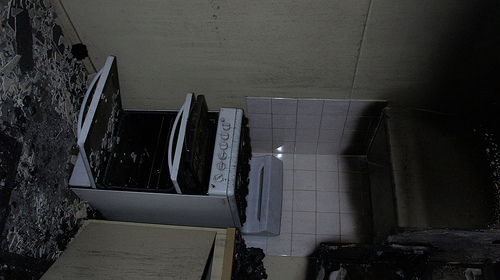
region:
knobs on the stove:
[213, 114, 232, 189]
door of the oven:
[252, 153, 284, 238]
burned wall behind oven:
[12, 38, 72, 130]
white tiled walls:
[280, 101, 340, 143]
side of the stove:
[107, 193, 190, 218]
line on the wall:
[335, 16, 378, 69]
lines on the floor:
[299, 161, 330, 216]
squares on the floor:
[291, 166, 319, 216]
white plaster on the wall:
[32, 65, 64, 99]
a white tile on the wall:
[245, 93, 272, 116]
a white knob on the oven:
[220, 118, 232, 133]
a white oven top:
[241, 148, 289, 240]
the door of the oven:
[66, 48, 134, 188]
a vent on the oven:
[258, 160, 268, 225]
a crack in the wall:
[344, 0, 377, 101]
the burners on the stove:
[228, 106, 255, 226]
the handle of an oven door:
[160, 100, 190, 175]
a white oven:
[58, 31, 296, 246]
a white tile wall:
[238, 85, 395, 263]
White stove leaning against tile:
[55, 54, 282, 237]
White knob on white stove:
[220, 119, 231, 132]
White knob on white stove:
[220, 129, 231, 141]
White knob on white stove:
[218, 138, 230, 150]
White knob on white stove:
[217, 148, 227, 162]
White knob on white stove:
[214, 157, 226, 172]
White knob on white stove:
[212, 170, 225, 183]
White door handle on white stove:
[166, 98, 183, 170]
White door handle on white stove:
[72, 60, 106, 137]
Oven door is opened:
[70, 47, 157, 189]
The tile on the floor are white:
[290, 159, 356, 229]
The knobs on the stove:
[213, 110, 233, 195]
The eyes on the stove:
[233, 108, 258, 230]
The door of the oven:
[73, 52, 130, 192]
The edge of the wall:
[374, 104, 407, 231]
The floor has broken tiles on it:
[4, 21, 71, 237]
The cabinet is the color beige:
[73, 212, 244, 277]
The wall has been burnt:
[303, 218, 493, 278]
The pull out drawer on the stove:
[164, 88, 213, 199]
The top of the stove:
[251, 144, 289, 241]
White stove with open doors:
[74, 56, 288, 238]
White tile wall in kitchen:
[238, 80, 394, 260]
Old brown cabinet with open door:
[34, 213, 274, 274]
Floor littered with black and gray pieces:
[12, 4, 74, 266]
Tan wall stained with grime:
[68, 7, 483, 103]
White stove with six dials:
[70, 50, 285, 237]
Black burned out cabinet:
[308, 223, 484, 278]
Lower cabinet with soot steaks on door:
[36, 210, 273, 279]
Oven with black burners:
[66, 43, 294, 235]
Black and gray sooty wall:
[369, 93, 494, 228]